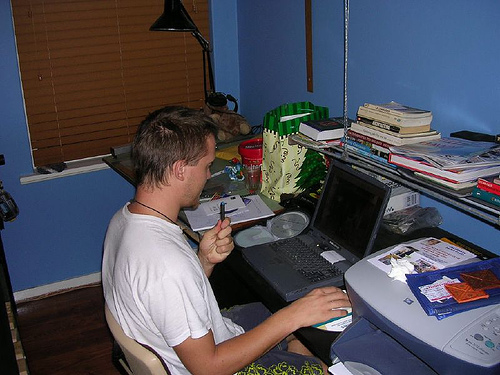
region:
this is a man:
[103, 110, 225, 337]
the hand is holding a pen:
[214, 199, 230, 227]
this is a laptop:
[318, 185, 360, 248]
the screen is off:
[326, 191, 371, 226]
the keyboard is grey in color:
[278, 234, 324, 279]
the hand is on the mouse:
[298, 285, 342, 328]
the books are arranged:
[351, 103, 431, 158]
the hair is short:
[134, 111, 202, 158]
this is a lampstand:
[148, 2, 202, 43]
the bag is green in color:
[263, 105, 299, 155]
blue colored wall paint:
[371, 33, 492, 92]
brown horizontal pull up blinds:
[29, 39, 179, 106]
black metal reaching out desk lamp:
[163, 10, 213, 62]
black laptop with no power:
[283, 174, 375, 318]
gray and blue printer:
[324, 231, 460, 371]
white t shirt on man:
[97, 213, 245, 365]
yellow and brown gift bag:
[261, 140, 324, 218]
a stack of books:
[357, 65, 417, 196]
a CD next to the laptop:
[268, 190, 325, 252]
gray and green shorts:
[272, 349, 302, 371]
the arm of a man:
[148, 245, 309, 370]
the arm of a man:
[192, 244, 217, 274]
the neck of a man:
[131, 176, 179, 219]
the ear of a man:
[174, 158, 186, 176]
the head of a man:
[132, 104, 217, 213]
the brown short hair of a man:
[134, 106, 211, 176]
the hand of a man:
[297, 282, 347, 328]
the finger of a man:
[310, 281, 343, 296]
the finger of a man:
[325, 289, 349, 301]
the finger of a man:
[329, 300, 354, 308]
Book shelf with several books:
[289, 101, 498, 224]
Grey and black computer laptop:
[241, 157, 390, 303]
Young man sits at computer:
[100, 105, 351, 371]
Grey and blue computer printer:
[328, 236, 498, 373]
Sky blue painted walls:
[0, 0, 498, 295]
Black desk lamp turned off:
[149, 1, 211, 112]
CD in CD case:
[234, 210, 308, 247]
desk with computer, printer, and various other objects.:
[102, 127, 496, 372]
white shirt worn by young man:
[102, 201, 244, 373]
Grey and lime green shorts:
[220, 303, 322, 373]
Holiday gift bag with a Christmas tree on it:
[249, 93, 329, 203]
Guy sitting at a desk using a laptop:
[91, 93, 375, 360]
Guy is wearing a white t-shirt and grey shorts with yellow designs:
[101, 90, 293, 374]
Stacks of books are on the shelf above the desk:
[298, 84, 499, 211]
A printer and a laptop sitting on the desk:
[230, 146, 498, 373]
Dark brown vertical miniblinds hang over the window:
[12, 1, 244, 168]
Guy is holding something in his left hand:
[110, 109, 242, 266]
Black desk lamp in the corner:
[141, 2, 278, 152]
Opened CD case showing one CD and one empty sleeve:
[227, 197, 307, 248]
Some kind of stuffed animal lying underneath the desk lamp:
[161, 9, 263, 138]